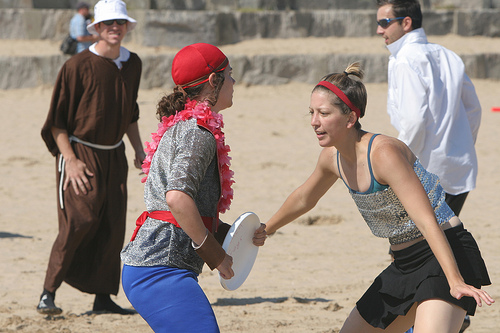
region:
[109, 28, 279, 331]
a girl holding a white frisbee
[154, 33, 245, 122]
a girl wearing a red hat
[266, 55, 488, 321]
a girl in a black skirt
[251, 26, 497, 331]
a girl blocking a frisbee throw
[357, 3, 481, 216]
a guy in sunglasses and white shirt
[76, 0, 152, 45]
a guy in a white hat and sun glasses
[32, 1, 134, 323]
a guy wearing brown cloth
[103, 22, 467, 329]
two girls playing frisbee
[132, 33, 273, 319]
girl trying to throw the frisbee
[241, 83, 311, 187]
dirt on a beach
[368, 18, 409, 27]
sunglasses on man's face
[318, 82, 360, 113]
red hair band in woman's hair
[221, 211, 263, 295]
white frisbee in girl's hand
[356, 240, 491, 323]
black skirt worn by woman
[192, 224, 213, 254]
white bracelet on wrist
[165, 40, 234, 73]
red stocking cap on head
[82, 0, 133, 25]
white bucket hat on head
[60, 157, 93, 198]
man in brown's right hand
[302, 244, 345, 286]
sand on the beach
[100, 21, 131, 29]
dark sunglasses on guy's face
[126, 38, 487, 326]
people playing game of frisbee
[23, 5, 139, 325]
man dressed in female dress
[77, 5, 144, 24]
hat on a woman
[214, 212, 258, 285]
frisbee between persons hands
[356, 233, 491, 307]
black skirt on woman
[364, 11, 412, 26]
sunglasses on man's face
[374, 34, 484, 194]
white shirt on man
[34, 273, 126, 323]
shoes on the man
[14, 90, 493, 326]
ground with sand and little grass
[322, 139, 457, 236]
top on the woman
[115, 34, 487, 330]
two women playing a frisbee game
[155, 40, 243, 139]
a woman wearing a red ball cap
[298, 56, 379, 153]
a woman wearing a red head band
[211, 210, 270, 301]
hands holding a white frisbee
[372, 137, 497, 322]
the arm of a woman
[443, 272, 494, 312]
the hand of a woman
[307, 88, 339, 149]
the face of a woman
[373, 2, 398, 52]
the face of a man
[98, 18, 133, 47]
the face of a man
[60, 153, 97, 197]
the hand of a man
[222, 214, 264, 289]
a white fisbee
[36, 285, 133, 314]
a pair of black socks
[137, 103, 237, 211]
a red and pink lei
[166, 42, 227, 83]
a tight red cap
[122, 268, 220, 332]
a pair of blue pants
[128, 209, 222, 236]
a red belt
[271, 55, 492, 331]
a girl wearing a red headband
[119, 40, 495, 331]
a girl gaurding someone with a frisbee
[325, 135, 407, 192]
part of a thin strapped shirt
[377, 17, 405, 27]
a pair of sunglass